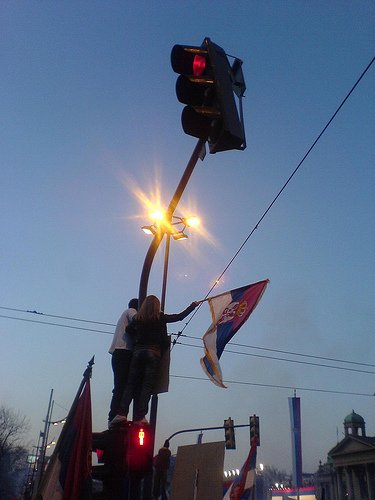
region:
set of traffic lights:
[167, 35, 246, 157]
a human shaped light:
[137, 428, 143, 445]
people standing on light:
[108, 294, 198, 425]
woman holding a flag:
[126, 278, 269, 425]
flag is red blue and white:
[198, 278, 270, 387]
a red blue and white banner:
[290, 395, 300, 490]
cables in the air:
[1, 59, 374, 396]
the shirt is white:
[108, 307, 135, 349]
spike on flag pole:
[87, 354, 96, 364]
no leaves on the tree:
[1, 405, 32, 475]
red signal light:
[161, 42, 237, 151]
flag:
[197, 260, 264, 405]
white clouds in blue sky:
[339, 236, 364, 282]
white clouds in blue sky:
[80, 136, 97, 161]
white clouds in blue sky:
[34, 192, 56, 220]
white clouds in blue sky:
[308, 174, 333, 213]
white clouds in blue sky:
[263, 36, 288, 62]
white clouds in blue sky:
[71, 57, 119, 98]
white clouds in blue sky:
[4, 74, 77, 158]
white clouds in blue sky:
[36, 200, 86, 250]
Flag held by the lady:
[196, 279, 273, 391]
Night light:
[123, 163, 221, 496]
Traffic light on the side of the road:
[87, 417, 159, 497]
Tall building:
[285, 385, 305, 497]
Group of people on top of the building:
[106, 279, 267, 423]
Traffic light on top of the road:
[172, 28, 250, 164]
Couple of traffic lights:
[221, 411, 264, 448]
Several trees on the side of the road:
[0, 405, 38, 498]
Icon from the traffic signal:
[134, 422, 148, 446]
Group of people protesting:
[107, 276, 270, 422]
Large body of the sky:
[22, 31, 139, 166]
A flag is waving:
[205, 274, 277, 388]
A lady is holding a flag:
[142, 278, 274, 420]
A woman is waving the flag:
[142, 274, 275, 417]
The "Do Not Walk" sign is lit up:
[131, 423, 149, 447]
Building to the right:
[316, 403, 369, 496]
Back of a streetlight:
[248, 413, 265, 445]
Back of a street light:
[222, 413, 238, 451]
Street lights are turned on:
[140, 202, 212, 245]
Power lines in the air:
[263, 342, 373, 380]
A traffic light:
[147, 16, 260, 151]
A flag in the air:
[193, 284, 283, 394]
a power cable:
[249, 150, 336, 225]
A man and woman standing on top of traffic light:
[91, 280, 174, 402]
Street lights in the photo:
[142, 194, 198, 244]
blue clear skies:
[297, 222, 356, 309]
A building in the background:
[320, 413, 371, 493]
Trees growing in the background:
[1, 417, 30, 485]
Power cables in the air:
[248, 335, 357, 399]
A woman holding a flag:
[134, 292, 270, 400]